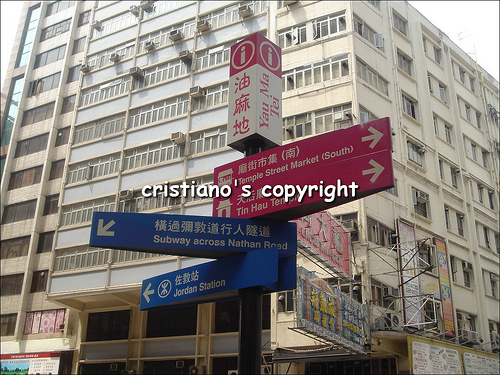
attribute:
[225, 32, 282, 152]
sign — red 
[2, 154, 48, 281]
concrete — off-white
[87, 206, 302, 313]
signs — blue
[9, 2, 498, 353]
building — tall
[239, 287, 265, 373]
pole — black 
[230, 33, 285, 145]
sign — red, white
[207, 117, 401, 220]
signs — Pink